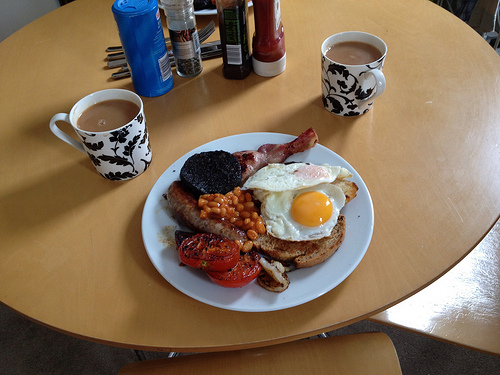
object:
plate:
[139, 131, 375, 313]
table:
[0, 0, 497, 360]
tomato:
[178, 233, 241, 273]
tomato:
[205, 249, 262, 288]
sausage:
[179, 149, 242, 197]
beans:
[233, 186, 243, 198]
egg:
[257, 181, 347, 243]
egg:
[239, 159, 353, 193]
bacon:
[257, 126, 320, 164]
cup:
[48, 88, 153, 182]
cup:
[319, 30, 387, 118]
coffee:
[75, 98, 141, 133]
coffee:
[325, 40, 382, 66]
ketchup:
[249, 0, 287, 79]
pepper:
[164, 0, 204, 78]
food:
[160, 126, 361, 293]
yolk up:
[290, 191, 333, 228]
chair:
[119, 331, 403, 375]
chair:
[363, 214, 500, 356]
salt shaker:
[109, 0, 175, 99]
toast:
[167, 178, 360, 269]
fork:
[105, 19, 217, 52]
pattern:
[321, 55, 386, 117]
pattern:
[75, 112, 152, 181]